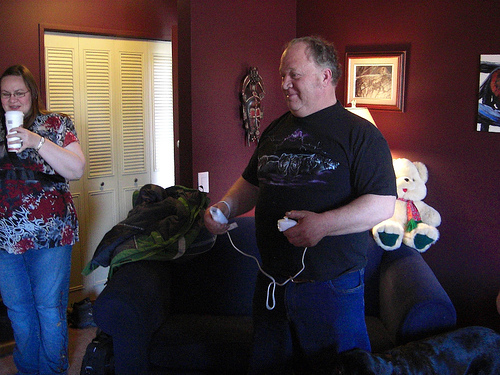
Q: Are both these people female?
A: No, they are both male and female.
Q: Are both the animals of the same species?
A: No, they are dogs and bears.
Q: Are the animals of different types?
A: Yes, they are dogs and bears.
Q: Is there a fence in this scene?
A: No, there are no fences.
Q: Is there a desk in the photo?
A: No, there are no desks.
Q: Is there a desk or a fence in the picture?
A: No, there are no desks or fences.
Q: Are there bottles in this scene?
A: No, there are no bottles.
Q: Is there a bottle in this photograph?
A: No, there are no bottles.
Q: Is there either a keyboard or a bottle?
A: No, there are no bottles or keyboards.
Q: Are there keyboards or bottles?
A: No, there are no bottles or keyboards.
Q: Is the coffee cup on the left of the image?
A: Yes, the coffee cup is on the left of the image.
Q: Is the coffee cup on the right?
A: No, the coffee cup is on the left of the image.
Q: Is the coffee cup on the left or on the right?
A: The coffee cup is on the left of the image.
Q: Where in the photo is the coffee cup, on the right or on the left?
A: The coffee cup is on the left of the image.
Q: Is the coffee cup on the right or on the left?
A: The coffee cup is on the left of the image.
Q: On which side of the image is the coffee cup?
A: The coffee cup is on the left of the image.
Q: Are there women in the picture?
A: Yes, there is a woman.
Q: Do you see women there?
A: Yes, there is a woman.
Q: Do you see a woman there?
A: Yes, there is a woman.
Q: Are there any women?
A: Yes, there is a woman.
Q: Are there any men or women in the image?
A: Yes, there is a woman.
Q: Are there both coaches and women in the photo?
A: No, there is a woman but no coaches.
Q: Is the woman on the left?
A: Yes, the woman is on the left of the image.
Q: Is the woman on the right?
A: No, the woman is on the left of the image.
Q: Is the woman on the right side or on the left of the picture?
A: The woman is on the left of the image.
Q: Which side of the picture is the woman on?
A: The woman is on the left of the image.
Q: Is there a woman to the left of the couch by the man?
A: Yes, there is a woman to the left of the couch.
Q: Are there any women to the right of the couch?
A: No, the woman is to the left of the couch.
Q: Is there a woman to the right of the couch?
A: No, the woman is to the left of the couch.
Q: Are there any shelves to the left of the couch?
A: No, there is a woman to the left of the couch.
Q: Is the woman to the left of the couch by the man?
A: Yes, the woman is to the left of the couch.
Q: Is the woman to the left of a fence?
A: No, the woman is to the left of the couch.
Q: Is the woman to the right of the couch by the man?
A: No, the woman is to the left of the couch.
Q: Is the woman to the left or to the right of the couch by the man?
A: The woman is to the left of the couch.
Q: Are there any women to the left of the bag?
A: Yes, there is a woman to the left of the bag.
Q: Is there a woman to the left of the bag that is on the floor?
A: Yes, there is a woman to the left of the bag.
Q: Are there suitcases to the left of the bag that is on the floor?
A: No, there is a woman to the left of the bag.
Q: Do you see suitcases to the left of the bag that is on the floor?
A: No, there is a woman to the left of the bag.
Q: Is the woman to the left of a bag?
A: Yes, the woman is to the left of a bag.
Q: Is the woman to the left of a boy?
A: No, the woman is to the left of a bag.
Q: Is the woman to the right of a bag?
A: No, the woman is to the left of a bag.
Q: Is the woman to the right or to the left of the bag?
A: The woman is to the left of the bag.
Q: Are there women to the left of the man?
A: Yes, there is a woman to the left of the man.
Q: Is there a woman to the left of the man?
A: Yes, there is a woman to the left of the man.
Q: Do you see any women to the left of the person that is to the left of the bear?
A: Yes, there is a woman to the left of the man.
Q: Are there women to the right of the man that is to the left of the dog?
A: No, the woman is to the left of the man.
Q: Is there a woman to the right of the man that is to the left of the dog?
A: No, the woman is to the left of the man.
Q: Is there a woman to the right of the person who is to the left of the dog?
A: No, the woman is to the left of the man.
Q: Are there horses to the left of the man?
A: No, there is a woman to the left of the man.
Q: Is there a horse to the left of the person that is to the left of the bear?
A: No, there is a woman to the left of the man.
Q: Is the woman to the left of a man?
A: Yes, the woman is to the left of a man.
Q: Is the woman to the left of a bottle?
A: No, the woman is to the left of a man.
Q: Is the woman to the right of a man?
A: No, the woman is to the left of a man.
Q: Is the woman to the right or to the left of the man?
A: The woman is to the left of the man.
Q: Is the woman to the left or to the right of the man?
A: The woman is to the left of the man.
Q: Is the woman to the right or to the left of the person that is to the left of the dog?
A: The woman is to the left of the man.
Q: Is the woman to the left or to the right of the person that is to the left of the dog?
A: The woman is to the left of the man.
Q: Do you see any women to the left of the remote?
A: Yes, there is a woman to the left of the remote.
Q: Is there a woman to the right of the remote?
A: No, the woman is to the left of the remote.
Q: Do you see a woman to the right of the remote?
A: No, the woman is to the left of the remote.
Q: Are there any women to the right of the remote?
A: No, the woman is to the left of the remote.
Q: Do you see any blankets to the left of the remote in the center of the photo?
A: No, there is a woman to the left of the remote.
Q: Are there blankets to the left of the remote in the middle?
A: No, there is a woman to the left of the remote.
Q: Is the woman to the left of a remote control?
A: Yes, the woman is to the left of a remote control.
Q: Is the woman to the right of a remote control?
A: No, the woman is to the left of a remote control.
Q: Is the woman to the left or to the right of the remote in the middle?
A: The woman is to the left of the remote.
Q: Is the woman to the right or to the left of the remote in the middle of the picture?
A: The woman is to the left of the remote.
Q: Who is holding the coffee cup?
A: The woman is holding the coffee cup.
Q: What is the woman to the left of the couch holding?
A: The woman is holding the coffee cup.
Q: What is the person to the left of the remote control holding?
A: The woman is holding the coffee cup.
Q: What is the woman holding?
A: The woman is holding the coffee cup.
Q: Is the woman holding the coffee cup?
A: Yes, the woman is holding the coffee cup.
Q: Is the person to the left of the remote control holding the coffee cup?
A: Yes, the woman is holding the coffee cup.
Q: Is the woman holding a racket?
A: No, the woman is holding the coffee cup.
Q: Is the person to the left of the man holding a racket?
A: No, the woman is holding the coffee cup.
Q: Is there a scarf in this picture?
A: Yes, there is a scarf.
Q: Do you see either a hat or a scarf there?
A: Yes, there is a scarf.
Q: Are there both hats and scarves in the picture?
A: No, there is a scarf but no hats.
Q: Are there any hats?
A: No, there are no hats.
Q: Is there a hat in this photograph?
A: No, there are no hats.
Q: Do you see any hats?
A: No, there are no hats.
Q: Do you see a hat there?
A: No, there are no hats.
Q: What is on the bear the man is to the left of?
A: The scarf is on the bear.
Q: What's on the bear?
A: The scarf is on the bear.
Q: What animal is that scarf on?
A: The scarf is on the bear.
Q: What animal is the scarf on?
A: The scarf is on the bear.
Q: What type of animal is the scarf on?
A: The scarf is on the bear.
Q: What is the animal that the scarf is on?
A: The animal is a bear.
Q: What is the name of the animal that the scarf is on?
A: The animal is a bear.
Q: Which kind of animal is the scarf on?
A: The scarf is on the bear.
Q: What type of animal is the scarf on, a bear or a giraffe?
A: The scarf is on a bear.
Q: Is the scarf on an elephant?
A: No, the scarf is on the bear.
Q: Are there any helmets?
A: No, there are no helmets.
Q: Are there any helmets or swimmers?
A: No, there are no helmets or swimmers.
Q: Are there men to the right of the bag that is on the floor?
A: Yes, there is a man to the right of the bag.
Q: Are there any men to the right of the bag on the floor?
A: Yes, there is a man to the right of the bag.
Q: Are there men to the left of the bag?
A: No, the man is to the right of the bag.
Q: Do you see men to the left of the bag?
A: No, the man is to the right of the bag.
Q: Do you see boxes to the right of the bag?
A: No, there is a man to the right of the bag.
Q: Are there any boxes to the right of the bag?
A: No, there is a man to the right of the bag.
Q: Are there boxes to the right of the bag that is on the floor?
A: No, there is a man to the right of the bag.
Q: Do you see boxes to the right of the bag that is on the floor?
A: No, there is a man to the right of the bag.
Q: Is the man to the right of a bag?
A: Yes, the man is to the right of a bag.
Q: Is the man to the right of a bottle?
A: No, the man is to the right of a bag.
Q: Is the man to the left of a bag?
A: No, the man is to the right of a bag.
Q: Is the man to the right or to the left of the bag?
A: The man is to the right of the bag.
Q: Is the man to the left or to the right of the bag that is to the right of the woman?
A: The man is to the right of the bag.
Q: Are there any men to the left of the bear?
A: Yes, there is a man to the left of the bear.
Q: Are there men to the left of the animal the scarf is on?
A: Yes, there is a man to the left of the bear.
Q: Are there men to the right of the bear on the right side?
A: No, the man is to the left of the bear.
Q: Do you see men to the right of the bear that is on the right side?
A: No, the man is to the left of the bear.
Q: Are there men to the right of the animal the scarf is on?
A: No, the man is to the left of the bear.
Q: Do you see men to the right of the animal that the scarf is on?
A: No, the man is to the left of the bear.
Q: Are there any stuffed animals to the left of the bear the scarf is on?
A: No, there is a man to the left of the bear.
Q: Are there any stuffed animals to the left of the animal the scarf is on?
A: No, there is a man to the left of the bear.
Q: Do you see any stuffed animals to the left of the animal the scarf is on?
A: No, there is a man to the left of the bear.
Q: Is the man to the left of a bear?
A: Yes, the man is to the left of a bear.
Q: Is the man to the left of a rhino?
A: No, the man is to the left of a bear.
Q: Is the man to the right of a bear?
A: No, the man is to the left of a bear.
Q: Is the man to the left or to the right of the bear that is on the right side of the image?
A: The man is to the left of the bear.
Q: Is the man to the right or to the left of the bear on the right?
A: The man is to the left of the bear.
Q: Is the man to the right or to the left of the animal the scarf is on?
A: The man is to the left of the bear.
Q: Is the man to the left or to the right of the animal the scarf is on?
A: The man is to the left of the bear.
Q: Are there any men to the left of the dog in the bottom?
A: Yes, there is a man to the left of the dog.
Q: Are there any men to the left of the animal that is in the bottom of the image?
A: Yes, there is a man to the left of the dog.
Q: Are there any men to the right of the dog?
A: No, the man is to the left of the dog.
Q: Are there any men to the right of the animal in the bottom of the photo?
A: No, the man is to the left of the dog.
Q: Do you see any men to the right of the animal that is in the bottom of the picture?
A: No, the man is to the left of the dog.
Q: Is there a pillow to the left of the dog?
A: No, there is a man to the left of the dog.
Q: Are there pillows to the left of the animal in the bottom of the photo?
A: No, there is a man to the left of the dog.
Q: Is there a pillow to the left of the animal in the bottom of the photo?
A: No, there is a man to the left of the dog.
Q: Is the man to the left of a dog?
A: Yes, the man is to the left of a dog.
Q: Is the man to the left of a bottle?
A: No, the man is to the left of a dog.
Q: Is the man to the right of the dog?
A: No, the man is to the left of the dog.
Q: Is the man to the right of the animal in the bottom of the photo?
A: No, the man is to the left of the dog.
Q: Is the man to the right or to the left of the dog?
A: The man is to the left of the dog.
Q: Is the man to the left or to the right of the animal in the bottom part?
A: The man is to the left of the dog.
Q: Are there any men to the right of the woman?
A: Yes, there is a man to the right of the woman.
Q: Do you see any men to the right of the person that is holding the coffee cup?
A: Yes, there is a man to the right of the woman.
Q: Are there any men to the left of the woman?
A: No, the man is to the right of the woman.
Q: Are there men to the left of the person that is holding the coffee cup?
A: No, the man is to the right of the woman.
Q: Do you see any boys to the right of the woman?
A: No, there is a man to the right of the woman.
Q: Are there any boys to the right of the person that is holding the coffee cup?
A: No, there is a man to the right of the woman.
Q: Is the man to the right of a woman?
A: Yes, the man is to the right of a woman.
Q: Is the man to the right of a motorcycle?
A: No, the man is to the right of a woman.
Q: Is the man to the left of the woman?
A: No, the man is to the right of the woman.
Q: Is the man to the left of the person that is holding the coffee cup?
A: No, the man is to the right of the woman.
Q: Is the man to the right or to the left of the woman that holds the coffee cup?
A: The man is to the right of the woman.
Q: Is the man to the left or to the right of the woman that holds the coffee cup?
A: The man is to the right of the woman.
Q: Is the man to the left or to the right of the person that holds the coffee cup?
A: The man is to the right of the woman.